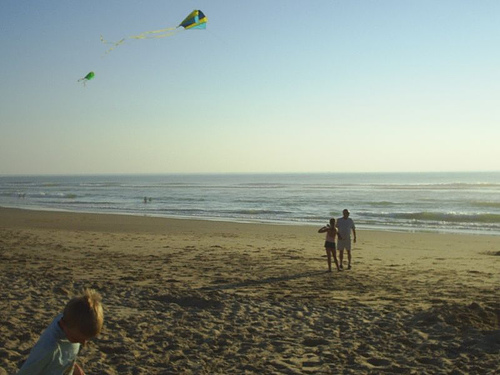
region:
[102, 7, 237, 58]
a kite in the sky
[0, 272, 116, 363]
little boy with blonde hair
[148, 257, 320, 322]
shadow on the ground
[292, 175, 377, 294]
two people on the beach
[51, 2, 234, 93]
two kites in the sky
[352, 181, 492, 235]
the waves are rolling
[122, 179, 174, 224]
people in the water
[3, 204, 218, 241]
the sand is wet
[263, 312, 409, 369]
foot prints in the sand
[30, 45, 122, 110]
the kite is green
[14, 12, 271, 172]
Kite in the sky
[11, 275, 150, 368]
Little boy playing on beach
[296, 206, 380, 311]
Man and girl on beach flying kite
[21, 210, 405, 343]
Beach with light brown sand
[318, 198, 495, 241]
Waves crashing against shore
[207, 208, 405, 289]
Two people flying a kite on the beach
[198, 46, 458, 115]
Blue cloudless sky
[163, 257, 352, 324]
Shadow of the people standing on beach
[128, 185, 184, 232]
Two people in the ocean water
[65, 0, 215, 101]
Kite is blue,yellow and tourquise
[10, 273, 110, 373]
The boy looking at the ground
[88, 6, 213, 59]
The kite with the yellow tail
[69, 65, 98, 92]
The green kite without a tail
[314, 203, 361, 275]
The two people standing next to each other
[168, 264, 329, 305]
The shadow of the two people standing next to each other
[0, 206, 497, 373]
The sand on the beach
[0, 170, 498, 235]
The water of the ocean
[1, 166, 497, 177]
The horizon line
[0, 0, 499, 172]
The sky the kites are in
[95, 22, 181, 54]
The yellow tail of a kite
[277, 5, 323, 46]
sky above the water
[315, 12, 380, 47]
blue sky above ocean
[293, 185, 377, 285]
two people on the beach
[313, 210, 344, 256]
person flying a kite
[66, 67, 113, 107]
kite in the air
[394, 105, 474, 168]
lightest part of the sky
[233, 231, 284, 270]
sand below the people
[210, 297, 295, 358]
footprints in the sand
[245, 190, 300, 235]
wave in the water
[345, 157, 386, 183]
ocean in the background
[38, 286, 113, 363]
a boy looking down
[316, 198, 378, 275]
two people standing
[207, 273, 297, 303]
a shadow on the sand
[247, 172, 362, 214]
the ocean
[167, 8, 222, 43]
a kite flying in the sky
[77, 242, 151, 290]
the sand is brown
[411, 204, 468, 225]
wave in the ocean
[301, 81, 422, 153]
The sky is bright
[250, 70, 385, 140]
the sky is clear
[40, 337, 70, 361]
boy wearing a grey shirt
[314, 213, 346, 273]
A person is standing up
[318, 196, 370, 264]
a person on the beach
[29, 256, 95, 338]
a person on the beach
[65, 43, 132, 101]
a kite in the sky